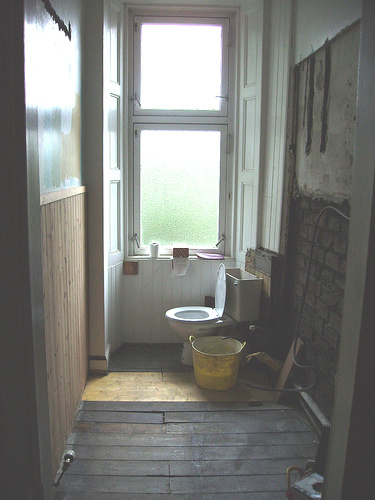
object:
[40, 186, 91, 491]
wood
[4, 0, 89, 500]
wall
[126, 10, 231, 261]
window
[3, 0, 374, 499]
bathroom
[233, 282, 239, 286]
flusher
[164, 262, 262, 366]
toilet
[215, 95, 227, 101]
knob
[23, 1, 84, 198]
top part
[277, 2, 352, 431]
wall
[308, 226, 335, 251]
brick area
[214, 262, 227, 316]
lid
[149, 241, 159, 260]
toilet paper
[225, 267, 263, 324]
toilet tank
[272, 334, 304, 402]
piece of wood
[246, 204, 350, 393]
cord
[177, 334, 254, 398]
bucket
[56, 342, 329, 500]
floor